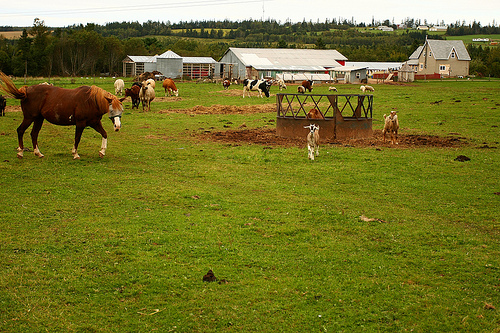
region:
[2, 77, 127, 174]
a brown horse in a farm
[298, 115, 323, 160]
a small goat walking around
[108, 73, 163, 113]
farm animals in a cluster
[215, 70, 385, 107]
cows and goats grazing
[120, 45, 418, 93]
barns and fences on a grass lot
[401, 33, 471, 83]
a small tan farm house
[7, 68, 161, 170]
The horse to the left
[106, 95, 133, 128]
The head of the horse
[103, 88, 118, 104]
The left ear of the horse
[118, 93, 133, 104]
The right ear of the horse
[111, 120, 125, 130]
The nose of the horse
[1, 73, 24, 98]
The tail of the horse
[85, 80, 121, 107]
The mane of the horse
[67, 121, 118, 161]
The front legs of the horse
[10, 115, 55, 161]
The back legs of the horse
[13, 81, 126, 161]
horse in a greed field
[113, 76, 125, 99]
horse in a greed field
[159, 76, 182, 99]
cow in a greed field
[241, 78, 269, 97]
cow in a greed field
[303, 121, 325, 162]
goat in a greed field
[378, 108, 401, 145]
goat in a greed field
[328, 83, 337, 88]
goat in a greed field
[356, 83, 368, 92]
goat in a greed field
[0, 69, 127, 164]
animal in green field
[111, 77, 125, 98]
animal in green field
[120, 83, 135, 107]
animal in green field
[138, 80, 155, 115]
animal in green field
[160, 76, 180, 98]
animal in green field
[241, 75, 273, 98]
animal in green field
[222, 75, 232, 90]
animal in green field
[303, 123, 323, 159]
animal in green field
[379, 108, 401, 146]
animal in green field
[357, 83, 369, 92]
animal in green field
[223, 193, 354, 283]
grass is green and short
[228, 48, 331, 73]
white barn in distance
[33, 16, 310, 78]
green trees behind barn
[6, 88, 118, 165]
brown horse on grass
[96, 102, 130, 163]
horse has white face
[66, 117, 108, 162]
horse has brown legs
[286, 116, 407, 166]
goats are on grass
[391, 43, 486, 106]
tan house next to barn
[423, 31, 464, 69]
house has grey roof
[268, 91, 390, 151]
brown pen next to goats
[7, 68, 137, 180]
the horse is brown